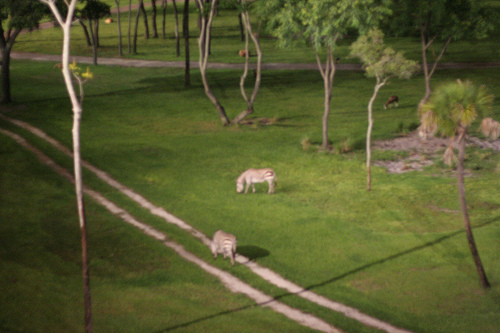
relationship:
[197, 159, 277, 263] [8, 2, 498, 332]
zebras on grass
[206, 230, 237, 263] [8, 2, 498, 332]
zebras on grass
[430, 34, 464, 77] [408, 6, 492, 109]
branch of tree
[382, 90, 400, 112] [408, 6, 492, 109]
animal near tree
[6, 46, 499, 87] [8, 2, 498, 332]
road thru grass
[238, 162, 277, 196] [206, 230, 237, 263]
zebra with zebras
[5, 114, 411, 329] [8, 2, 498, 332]
tracks in grass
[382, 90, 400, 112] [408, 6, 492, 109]
animal by tree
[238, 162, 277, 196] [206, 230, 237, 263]
zebra beside zebras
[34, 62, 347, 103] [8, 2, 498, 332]
shadows on grass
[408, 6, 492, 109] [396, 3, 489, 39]
tree has leaves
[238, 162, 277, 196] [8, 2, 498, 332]
zebra on grass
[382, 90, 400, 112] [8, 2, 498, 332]
animal on grass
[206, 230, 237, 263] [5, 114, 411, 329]
zebras on tracks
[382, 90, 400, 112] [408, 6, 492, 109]
animal standing under tree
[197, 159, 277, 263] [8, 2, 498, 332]
zebras in grass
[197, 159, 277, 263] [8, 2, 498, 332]
zebras grazing on grass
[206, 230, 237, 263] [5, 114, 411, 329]
zebras standing on tracks